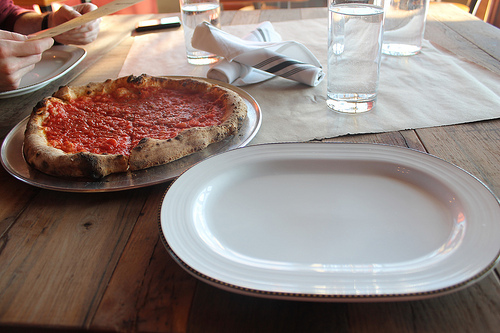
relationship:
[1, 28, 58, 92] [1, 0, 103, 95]
hand of person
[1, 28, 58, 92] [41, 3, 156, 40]
hand on menu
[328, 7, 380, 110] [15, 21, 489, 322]
water on table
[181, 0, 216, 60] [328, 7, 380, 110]
glass of water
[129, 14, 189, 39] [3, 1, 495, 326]
cell phone on table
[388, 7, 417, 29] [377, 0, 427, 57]
water in glass